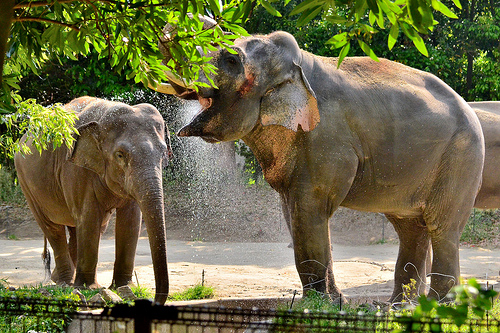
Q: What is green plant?
A: Tree.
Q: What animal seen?
A: Elephant.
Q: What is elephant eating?
A: Leaves.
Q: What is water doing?
A: Splashing.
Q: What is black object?
A: Fence.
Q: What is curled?
A: Trunk.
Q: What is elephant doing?
A: Walking.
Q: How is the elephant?
A: Dirty.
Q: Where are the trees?
A: In foreground.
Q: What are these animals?
A: Elephants.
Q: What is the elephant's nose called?
A: Trunk.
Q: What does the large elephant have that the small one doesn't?
A: Tusks.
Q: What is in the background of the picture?
A: Dense trees.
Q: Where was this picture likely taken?
A: Zoo.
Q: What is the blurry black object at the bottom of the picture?
A: Fence.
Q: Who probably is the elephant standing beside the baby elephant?
A: Mother elephant.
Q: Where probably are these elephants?
A: Zoo.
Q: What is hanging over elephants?
A: Branches.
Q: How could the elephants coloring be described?
A: Gray.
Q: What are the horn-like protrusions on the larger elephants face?
A: Tusks.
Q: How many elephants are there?
A: 2.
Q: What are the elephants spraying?
A: Water.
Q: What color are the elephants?
A: Grey.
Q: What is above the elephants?
A: Trees.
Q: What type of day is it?
A: Daytime.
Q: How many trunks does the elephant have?
A: 1.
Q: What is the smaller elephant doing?
A: Walking.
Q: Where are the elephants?
A: In a zoo.